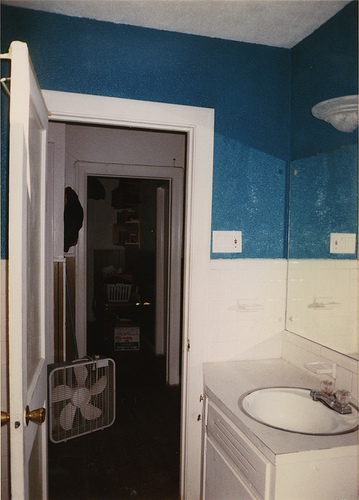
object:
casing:
[78, 147, 175, 181]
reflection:
[311, 94, 359, 134]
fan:
[47, 357, 117, 443]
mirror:
[284, 145, 359, 360]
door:
[6, 43, 53, 500]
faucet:
[310, 380, 352, 415]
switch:
[212, 231, 243, 254]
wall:
[167, 169, 287, 323]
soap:
[304, 362, 337, 375]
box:
[46, 356, 116, 444]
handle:
[24, 405, 46, 427]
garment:
[64, 186, 84, 252]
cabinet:
[188, 350, 359, 499]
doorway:
[41, 136, 212, 440]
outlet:
[212, 230, 242, 253]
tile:
[228, 268, 265, 304]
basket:
[113, 327, 140, 352]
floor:
[122, 425, 155, 494]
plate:
[242, 387, 359, 436]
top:
[207, 352, 356, 464]